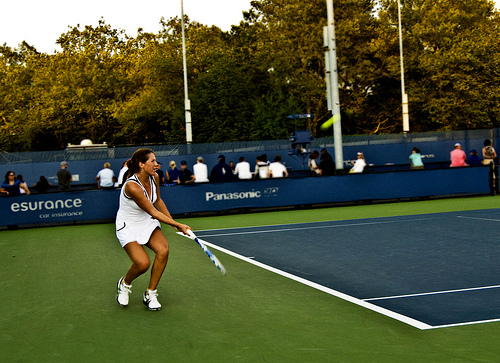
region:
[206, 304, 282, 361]
The grass is green.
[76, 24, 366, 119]
The trees are green.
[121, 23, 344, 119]
The trees have leaves.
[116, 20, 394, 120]
Trees are in the background.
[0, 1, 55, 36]
The sky is white.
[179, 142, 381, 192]
People are in the background.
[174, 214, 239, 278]
The person is holding a tennis racket.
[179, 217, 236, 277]
The tennis racket is white.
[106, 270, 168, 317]
The person is wearing tennis shoes.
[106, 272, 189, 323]
The tennis shoes are white.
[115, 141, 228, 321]
woman playing tennis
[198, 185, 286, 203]
panasonic advertisement on tennis court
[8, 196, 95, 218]
esurance advertisement on tennis court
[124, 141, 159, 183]
woman wearing her hair in a ponytail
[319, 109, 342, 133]
tennis ball flying through the air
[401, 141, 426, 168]
person wearing a blue shirt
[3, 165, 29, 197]
woman wearing a blue shirt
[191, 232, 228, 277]
blue and silver tennis racket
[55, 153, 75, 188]
person wearing a ball cap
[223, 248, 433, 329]
boundary line on tennis court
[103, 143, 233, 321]
Woman playing tennis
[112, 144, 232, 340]
Woman wearing white tennis outfit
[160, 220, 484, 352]
Blue and green tennis court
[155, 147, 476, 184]
People standing beside a tennis court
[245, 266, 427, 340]
White lines on a tennis court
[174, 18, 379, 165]
Tall light poles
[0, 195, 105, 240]
Advertisement on a wall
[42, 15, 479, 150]
A row of large trees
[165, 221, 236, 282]
Tennis racket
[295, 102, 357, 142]
Tennis ball in flight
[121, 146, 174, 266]
White tennis outfit on woman.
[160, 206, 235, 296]
Blue and white tennis racquet in hands.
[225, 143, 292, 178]
Back of people on benches.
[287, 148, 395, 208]
Blue separating wall on court.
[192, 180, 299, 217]
Advertisement on blue wall.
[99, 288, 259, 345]
Green artificial turf on ground.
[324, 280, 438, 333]
White lines on tennis court.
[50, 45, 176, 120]
Fall coloring on trees.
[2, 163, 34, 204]
Woman leaning on fence.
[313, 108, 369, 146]
Tennis ball in motion.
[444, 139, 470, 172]
This is a person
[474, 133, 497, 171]
This is a person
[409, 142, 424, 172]
This is a person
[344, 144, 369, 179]
This is a person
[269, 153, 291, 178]
This is a person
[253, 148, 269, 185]
This is a person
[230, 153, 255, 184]
This is a person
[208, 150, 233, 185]
This is a person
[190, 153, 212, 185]
This is a person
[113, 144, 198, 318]
This is a person